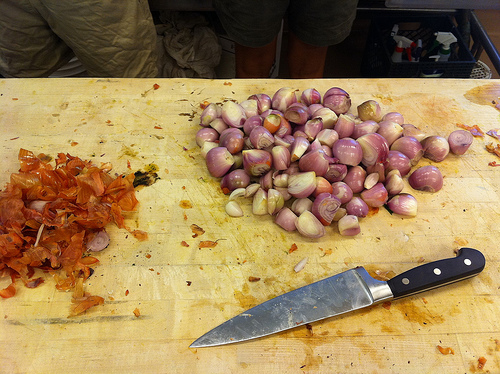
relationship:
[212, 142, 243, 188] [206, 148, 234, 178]
piece of cut shallot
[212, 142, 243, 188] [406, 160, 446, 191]
piece of cut shallot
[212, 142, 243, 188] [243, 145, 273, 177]
piece of cut shallot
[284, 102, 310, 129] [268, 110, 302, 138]
piece of shallot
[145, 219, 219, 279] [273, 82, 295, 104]
small piece of shallot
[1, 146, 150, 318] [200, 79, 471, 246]
skins from onions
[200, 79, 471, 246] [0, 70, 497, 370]
onions on cutting board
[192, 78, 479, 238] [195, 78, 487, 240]
pile of onions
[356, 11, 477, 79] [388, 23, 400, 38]
container holding products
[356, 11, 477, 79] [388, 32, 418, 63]
container holding products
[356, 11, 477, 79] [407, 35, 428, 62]
container holding products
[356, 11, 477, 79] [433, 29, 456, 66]
container holding products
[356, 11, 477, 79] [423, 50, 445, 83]
container holding products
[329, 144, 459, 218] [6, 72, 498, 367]
onion on board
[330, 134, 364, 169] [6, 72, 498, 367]
onion on board